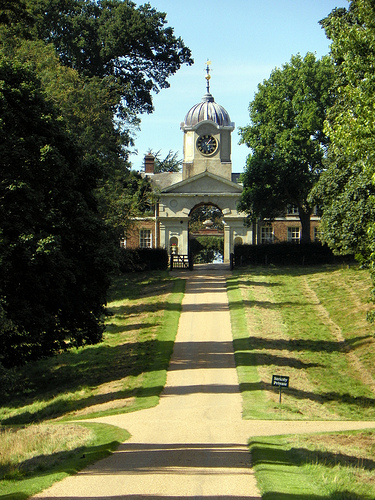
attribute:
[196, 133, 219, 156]
clock — black, white, here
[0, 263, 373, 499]
grass — short, brown, green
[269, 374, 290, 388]
sign — small, black, white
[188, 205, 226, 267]
entrance — open, here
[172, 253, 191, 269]
gate — open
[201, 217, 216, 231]
fountain — distant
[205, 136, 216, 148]
clock hands — gold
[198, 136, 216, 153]
numbers — gold, roman numerals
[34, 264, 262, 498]
path — long, beige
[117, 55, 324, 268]
building — brick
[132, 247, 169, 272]
shrub — here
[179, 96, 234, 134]
roof — gray, dome-shaped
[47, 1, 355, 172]
sky — clear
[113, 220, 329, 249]
wall — brown brick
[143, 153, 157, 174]
chimney — red brick